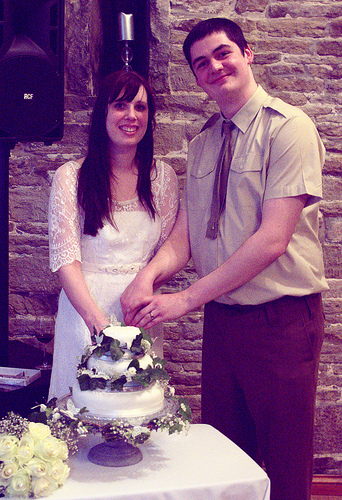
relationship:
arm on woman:
[45, 193, 92, 321] [45, 70, 178, 222]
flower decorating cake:
[88, 326, 109, 352] [68, 319, 172, 423]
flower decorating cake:
[78, 363, 110, 389] [68, 319, 172, 423]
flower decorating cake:
[158, 398, 193, 434] [68, 319, 172, 423]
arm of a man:
[119, 196, 226, 310] [127, 2, 329, 499]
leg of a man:
[197, 340, 252, 455] [167, 15, 333, 498]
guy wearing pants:
[119, 18, 329, 498] [174, 308, 305, 476]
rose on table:
[0, 451, 26, 486] [66, 443, 260, 497]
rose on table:
[28, 457, 51, 478] [66, 443, 260, 497]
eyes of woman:
[110, 96, 152, 114] [44, 68, 183, 408]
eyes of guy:
[192, 44, 239, 68] [119, 18, 329, 498]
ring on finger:
[149, 311, 154, 319] [132, 306, 158, 327]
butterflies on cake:
[59, 309, 226, 444] [56, 313, 207, 453]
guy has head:
[119, 14, 329, 499] [157, 10, 329, 253]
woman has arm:
[44, 68, 173, 395] [50, 168, 110, 335]